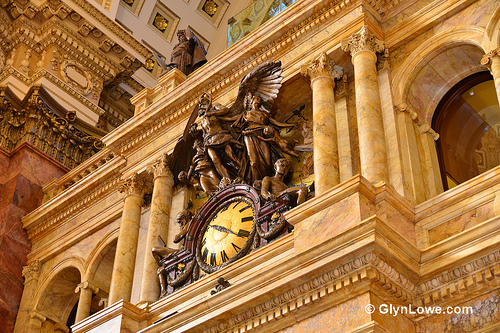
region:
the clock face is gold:
[173, 180, 288, 281]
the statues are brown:
[144, 63, 329, 231]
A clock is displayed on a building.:
[168, 190, 291, 285]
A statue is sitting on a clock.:
[257, 157, 316, 212]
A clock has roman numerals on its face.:
[168, 203, 270, 285]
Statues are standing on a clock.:
[158, 93, 293, 165]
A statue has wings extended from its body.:
[183, 55, 292, 138]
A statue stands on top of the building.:
[141, 26, 222, 84]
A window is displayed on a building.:
[401, 61, 496, 180]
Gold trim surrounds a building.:
[16, 93, 100, 155]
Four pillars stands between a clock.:
[118, 125, 390, 309]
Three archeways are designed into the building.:
[32, 104, 493, 326]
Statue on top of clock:
[133, 63, 323, 248]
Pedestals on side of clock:
[284, 47, 463, 332]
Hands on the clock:
[194, 208, 239, 245]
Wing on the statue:
[208, 48, 277, 136]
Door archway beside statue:
[400, 23, 484, 138]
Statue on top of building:
[152, 24, 219, 79]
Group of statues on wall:
[31, 100, 101, 185]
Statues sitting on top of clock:
[170, 156, 322, 235]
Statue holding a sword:
[125, 25, 195, 78]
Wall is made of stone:
[301, 38, 419, 243]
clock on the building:
[188, 186, 256, 272]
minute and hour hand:
[202, 220, 242, 240]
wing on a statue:
[242, 60, 283, 103]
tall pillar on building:
[358, 53, 384, 184]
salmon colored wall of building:
[2, 156, 56, 209]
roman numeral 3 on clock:
[240, 211, 254, 223]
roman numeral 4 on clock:
[233, 224, 252, 244]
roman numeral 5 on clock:
[228, 242, 247, 256]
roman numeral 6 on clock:
[219, 249, 231, 267]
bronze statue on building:
[180, 90, 239, 188]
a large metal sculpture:
[141, 56, 346, 298]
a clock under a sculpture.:
[189, 172, 267, 277]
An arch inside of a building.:
[390, 15, 498, 215]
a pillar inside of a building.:
[124, 62, 191, 117]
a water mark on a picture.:
[351, 291, 488, 331]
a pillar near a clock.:
[129, 145, 196, 305]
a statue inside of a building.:
[160, 23, 215, 84]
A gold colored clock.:
[190, 188, 278, 275]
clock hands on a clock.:
[201, 208, 245, 239]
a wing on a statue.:
[229, 60, 299, 117]